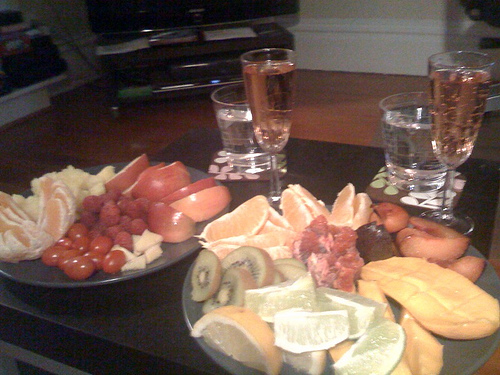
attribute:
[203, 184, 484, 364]
plate — grey 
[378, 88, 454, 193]
glass — full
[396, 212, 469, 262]
peach — sliced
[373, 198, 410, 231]
peach — sliced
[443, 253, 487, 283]
peach — sliced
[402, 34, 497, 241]
glass — full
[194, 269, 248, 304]
kiwi — sliced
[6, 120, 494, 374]
table — black, coffee table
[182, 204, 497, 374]
plate — grey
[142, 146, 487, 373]
plate — grey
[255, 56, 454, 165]
floor — wooden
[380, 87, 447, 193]
glass — clear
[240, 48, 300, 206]
glass — full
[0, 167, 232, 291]
plate — grey 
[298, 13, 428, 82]
baseboard — White 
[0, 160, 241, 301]
plate — grey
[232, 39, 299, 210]
glass — clear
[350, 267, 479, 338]
bread — sliced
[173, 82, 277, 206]
glass — clear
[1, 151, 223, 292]
plate — fruit plates, fruit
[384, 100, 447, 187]
glass — clear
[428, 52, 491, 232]
glass — clear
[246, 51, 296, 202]
glass — clear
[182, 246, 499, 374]
plate — gray